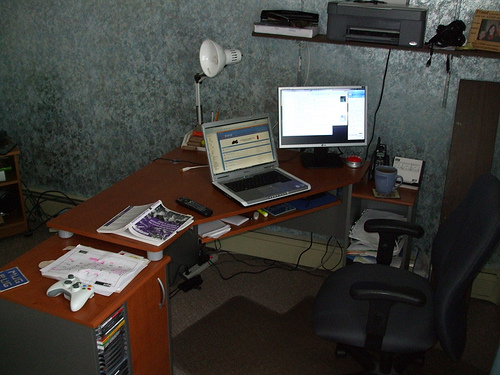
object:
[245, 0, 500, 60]
shelf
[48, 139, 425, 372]
corner desk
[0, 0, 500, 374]
room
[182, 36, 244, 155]
white lamp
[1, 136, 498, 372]
desk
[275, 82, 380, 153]
monitor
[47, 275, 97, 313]
controller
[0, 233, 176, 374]
file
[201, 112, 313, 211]
laptop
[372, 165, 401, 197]
cup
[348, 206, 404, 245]
papers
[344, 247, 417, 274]
shelf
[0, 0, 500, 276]
wall